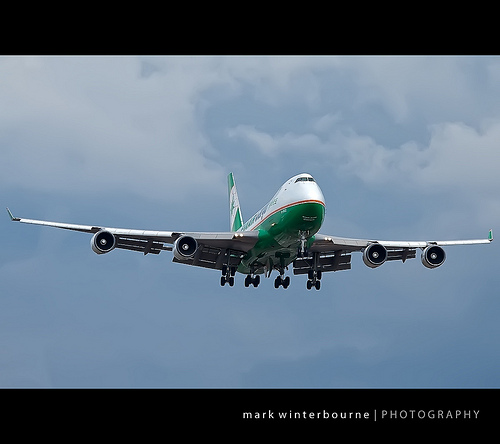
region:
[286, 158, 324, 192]
WINDOWS FOR PILOTS VIEW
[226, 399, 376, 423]
NAME OF PHOTOGRAPHER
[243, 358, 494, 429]
PICTURE TAKEN BY A PROFESSION PHOTOGRAPHER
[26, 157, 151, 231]
PARTLY CLOUDY SKIES DURING FLIGHT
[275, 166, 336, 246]
GREEN RED AND WHITE COLORS DECORATE THIS JUMBO JET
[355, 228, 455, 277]
JET PROPULSION ENGINES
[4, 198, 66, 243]
WING TIPS POINT UPWARDS ON THIS JET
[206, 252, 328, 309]
WHEELS ARE DOWN FOR JET LANDING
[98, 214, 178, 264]
WING FLAPS ARE DOWN FOR LANDING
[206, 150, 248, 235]
GREEN AND WHITE TAIL ON JUMBO JET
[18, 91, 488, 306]
A jet airliner.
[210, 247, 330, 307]
Landing gear is in the down position.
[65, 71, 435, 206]
A dark and cloudy sky.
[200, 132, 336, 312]
The plane is green and white.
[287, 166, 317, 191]
The cockpit of the plane.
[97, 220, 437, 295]
The plane's flaps are being used.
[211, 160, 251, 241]
The vertical stabilizer of the plane.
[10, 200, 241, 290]
Two engines on the plane's right wing.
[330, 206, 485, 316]
Two engines on the plane's left wing.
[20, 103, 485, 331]
The plane is in the process of landing.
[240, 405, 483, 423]
The name of the person that took the photo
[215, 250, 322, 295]
Landing gear of the plane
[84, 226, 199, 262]
Engines on the plane's right wing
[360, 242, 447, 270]
Engines on the left wing of the plane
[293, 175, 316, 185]
The pilot's wind shield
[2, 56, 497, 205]
Clouds in the sky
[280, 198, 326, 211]
Red strip on the nose of the plane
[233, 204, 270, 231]
Name of the airline on the side of the plane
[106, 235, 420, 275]
Brakes deployed under the wings of the plane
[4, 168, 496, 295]
Commercial airliner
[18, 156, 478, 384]
Picture is taken outside.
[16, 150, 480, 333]
The plane is flying in the air.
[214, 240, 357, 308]
The plane's landing gear is down.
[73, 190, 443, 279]
The plane has four engines.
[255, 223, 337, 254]
The belly of the plane is green in color.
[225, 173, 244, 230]
The tail of the plane is green and whie in color.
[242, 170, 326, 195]
The upper portion of the plane is white in color.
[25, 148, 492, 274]
Picture of plane taken during a sunny day.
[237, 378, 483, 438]
The name of the photographer is Mark Winterbourne.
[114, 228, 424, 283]
The wing flaps of the plane are down.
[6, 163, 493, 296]
a jumbo jet in flight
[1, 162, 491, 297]
a jumbo jet preparing to land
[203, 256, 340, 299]
landing gear is extended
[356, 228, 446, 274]
two jet engines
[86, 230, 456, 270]
four jet engines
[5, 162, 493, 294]
a green and white jet plane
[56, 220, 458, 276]
ailerons in the down position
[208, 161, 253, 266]
the tail of a jet plane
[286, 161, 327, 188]
windows for the pilots to use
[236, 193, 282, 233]
windows for the passengers